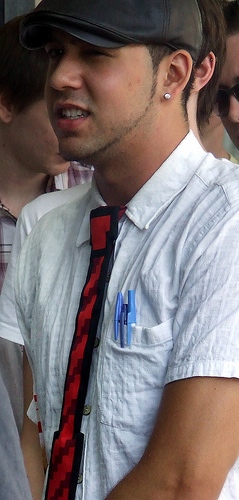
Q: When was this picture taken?
A: Daytime.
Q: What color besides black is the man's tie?
A: Red.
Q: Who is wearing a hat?
A: Guy with tie.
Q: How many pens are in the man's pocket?
A: Three.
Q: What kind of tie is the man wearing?
A: Clip on.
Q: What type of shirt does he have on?
A: Button up.